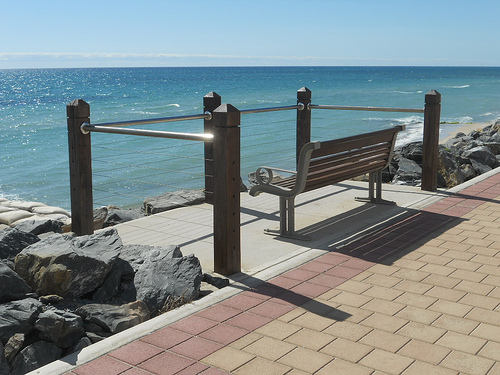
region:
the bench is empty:
[227, 109, 412, 203]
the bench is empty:
[252, 80, 416, 250]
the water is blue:
[51, 45, 129, 120]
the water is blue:
[87, 73, 198, 142]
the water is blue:
[28, 74, 186, 168]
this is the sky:
[223, 3, 270, 25]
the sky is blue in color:
[296, 7, 340, 33]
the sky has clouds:
[221, 46, 259, 63]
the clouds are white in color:
[133, 48, 179, 60]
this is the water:
[103, 68, 157, 105]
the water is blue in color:
[136, 70, 175, 105]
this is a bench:
[253, 123, 413, 238]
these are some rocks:
[5, 226, 195, 343]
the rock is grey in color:
[153, 265, 171, 291]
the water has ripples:
[126, 72, 172, 98]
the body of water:
[0, 65, 499, 212]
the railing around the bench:
[67, 85, 440, 275]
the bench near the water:
[249, 123, 407, 241]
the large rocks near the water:
[0, 114, 498, 372]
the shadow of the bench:
[272, 195, 469, 266]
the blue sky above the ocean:
[0, 0, 499, 67]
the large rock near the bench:
[13, 226, 123, 298]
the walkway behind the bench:
[24, 164, 499, 373]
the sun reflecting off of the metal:
[191, 130, 213, 140]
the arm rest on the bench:
[255, 165, 298, 185]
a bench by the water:
[240, 130, 405, 227]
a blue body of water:
[13, 59, 481, 168]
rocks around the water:
[12, 233, 168, 309]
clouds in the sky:
[8, 35, 255, 70]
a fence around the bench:
[68, 98, 452, 213]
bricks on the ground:
[107, 189, 492, 372]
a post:
[214, 108, 245, 278]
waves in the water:
[376, 103, 449, 153]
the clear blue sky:
[296, 37, 452, 55]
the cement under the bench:
[169, 201, 285, 257]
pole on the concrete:
[208, 108, 242, 275]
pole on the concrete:
[66, 100, 96, 237]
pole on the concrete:
[291, 83, 313, 150]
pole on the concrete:
[422, 93, 442, 191]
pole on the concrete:
[206, 89, 216, 204]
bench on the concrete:
[248, 123, 403, 230]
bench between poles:
[250, 121, 415, 235]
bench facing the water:
[247, 115, 407, 233]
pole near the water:
[62, 94, 99, 233]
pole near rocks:
[61, 100, 101, 233]